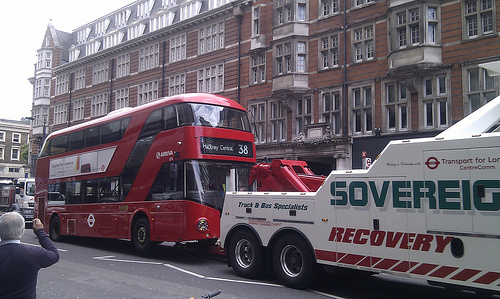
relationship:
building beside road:
[27, 1, 498, 179] [18, 216, 374, 296]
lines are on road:
[151, 258, 215, 286] [20, 229, 390, 293]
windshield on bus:
[181, 154, 256, 209] [35, 98, 255, 250]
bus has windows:
[35, 98, 255, 250] [35, 173, 139, 205]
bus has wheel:
[33, 91, 258, 256] [129, 203, 155, 256]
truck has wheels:
[215, 95, 497, 295] [221, 220, 321, 282]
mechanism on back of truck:
[271, 159, 309, 192] [248, 156, 328, 194]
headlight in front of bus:
[193, 215, 209, 235] [35, 98, 255, 250]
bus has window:
[33, 91, 258, 256] [181, 97, 263, 127]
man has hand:
[4, 209, 59, 274] [33, 214, 63, 264]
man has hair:
[1, 207, 63, 297] [1, 210, 26, 239]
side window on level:
[58, 175, 83, 198] [37, 167, 247, 247]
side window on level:
[89, 179, 119, 200] [37, 167, 247, 247]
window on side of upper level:
[48, 129, 69, 156] [35, 90, 254, 182]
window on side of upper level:
[68, 130, 83, 152] [35, 90, 254, 182]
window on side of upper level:
[85, 122, 99, 149] [35, 90, 254, 182]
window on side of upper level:
[100, 118, 120, 143] [35, 90, 254, 182]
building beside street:
[27, 1, 498, 179] [17, 225, 443, 297]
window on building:
[114, 48, 131, 85] [27, 1, 498, 179]